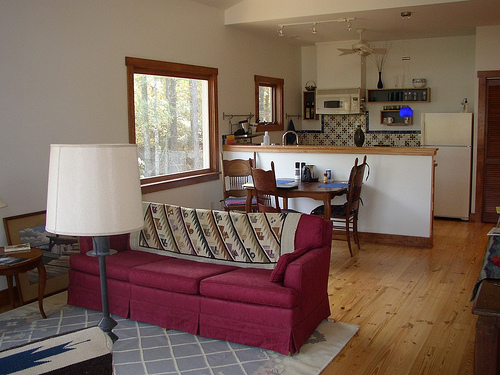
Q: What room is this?
A: It is a kitchen.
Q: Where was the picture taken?
A: It was taken at the kitchen.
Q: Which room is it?
A: It is a kitchen.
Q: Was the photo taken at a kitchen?
A: Yes, it was taken in a kitchen.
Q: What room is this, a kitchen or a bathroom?
A: It is a kitchen.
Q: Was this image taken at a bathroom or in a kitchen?
A: It was taken at a kitchen.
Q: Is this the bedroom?
A: No, it is the kitchen.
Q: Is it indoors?
A: Yes, it is indoors.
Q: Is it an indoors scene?
A: Yes, it is indoors.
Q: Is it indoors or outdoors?
A: It is indoors.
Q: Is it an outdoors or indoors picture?
A: It is indoors.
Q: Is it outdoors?
A: No, it is indoors.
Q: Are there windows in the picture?
A: Yes, there is a window.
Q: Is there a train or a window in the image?
A: Yes, there is a window.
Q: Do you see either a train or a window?
A: Yes, there is a window.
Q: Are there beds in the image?
A: No, there are no beds.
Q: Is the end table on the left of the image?
A: Yes, the end table is on the left of the image.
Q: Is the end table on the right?
A: No, the end table is on the left of the image.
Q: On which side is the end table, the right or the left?
A: The end table is on the left of the image.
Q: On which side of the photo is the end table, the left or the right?
A: The end table is on the left of the image.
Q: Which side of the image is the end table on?
A: The end table is on the left of the image.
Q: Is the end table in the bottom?
A: Yes, the end table is in the bottom of the image.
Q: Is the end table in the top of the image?
A: No, the end table is in the bottom of the image.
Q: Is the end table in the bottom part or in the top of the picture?
A: The end table is in the bottom of the image.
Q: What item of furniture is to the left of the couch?
A: The piece of furniture is an end table.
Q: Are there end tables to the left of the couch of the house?
A: Yes, there is an end table to the left of the couch.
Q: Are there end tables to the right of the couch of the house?
A: No, the end table is to the left of the couch.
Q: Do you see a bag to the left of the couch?
A: No, there is an end table to the left of the couch.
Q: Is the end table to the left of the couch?
A: Yes, the end table is to the left of the couch.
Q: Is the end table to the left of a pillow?
A: No, the end table is to the left of the couch.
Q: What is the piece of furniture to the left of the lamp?
A: The piece of furniture is an end table.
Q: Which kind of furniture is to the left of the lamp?
A: The piece of furniture is an end table.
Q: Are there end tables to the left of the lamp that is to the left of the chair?
A: Yes, there is an end table to the left of the lamp.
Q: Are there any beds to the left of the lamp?
A: No, there is an end table to the left of the lamp.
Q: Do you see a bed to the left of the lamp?
A: No, there is an end table to the left of the lamp.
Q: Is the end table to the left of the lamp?
A: Yes, the end table is to the left of the lamp.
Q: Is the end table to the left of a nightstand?
A: No, the end table is to the left of the lamp.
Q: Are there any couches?
A: Yes, there is a couch.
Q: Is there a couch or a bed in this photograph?
A: Yes, there is a couch.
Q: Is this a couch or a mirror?
A: This is a couch.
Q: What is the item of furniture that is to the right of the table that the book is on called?
A: The piece of furniture is a couch.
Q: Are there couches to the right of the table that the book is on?
A: Yes, there is a couch to the right of the table.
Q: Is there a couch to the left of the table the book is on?
A: No, the couch is to the right of the table.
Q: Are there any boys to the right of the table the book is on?
A: No, there is a couch to the right of the table.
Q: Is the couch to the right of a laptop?
A: No, the couch is to the right of the table.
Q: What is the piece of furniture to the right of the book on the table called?
A: The piece of furniture is a couch.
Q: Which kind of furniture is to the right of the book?
A: The piece of furniture is a couch.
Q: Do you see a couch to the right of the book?
A: Yes, there is a couch to the right of the book.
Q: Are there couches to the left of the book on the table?
A: No, the couch is to the right of the book.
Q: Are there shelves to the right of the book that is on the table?
A: No, there is a couch to the right of the book.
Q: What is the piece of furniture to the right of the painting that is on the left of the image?
A: The piece of furniture is a couch.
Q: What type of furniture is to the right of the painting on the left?
A: The piece of furniture is a couch.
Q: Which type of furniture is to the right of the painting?
A: The piece of furniture is a couch.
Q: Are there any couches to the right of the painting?
A: Yes, there is a couch to the right of the painting.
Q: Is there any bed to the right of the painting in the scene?
A: No, there is a couch to the right of the painting.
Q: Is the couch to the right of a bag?
A: No, the couch is to the right of a painting.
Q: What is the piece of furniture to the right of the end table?
A: The piece of furniture is a couch.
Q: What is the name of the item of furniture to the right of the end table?
A: The piece of furniture is a couch.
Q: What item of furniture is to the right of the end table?
A: The piece of furniture is a couch.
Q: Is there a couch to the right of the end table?
A: Yes, there is a couch to the right of the end table.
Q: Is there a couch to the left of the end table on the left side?
A: No, the couch is to the right of the end table.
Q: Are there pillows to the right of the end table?
A: No, there is a couch to the right of the end table.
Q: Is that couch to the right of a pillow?
A: No, the couch is to the right of an end table.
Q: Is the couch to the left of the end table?
A: No, the couch is to the right of the end table.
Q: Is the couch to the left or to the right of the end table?
A: The couch is to the right of the end table.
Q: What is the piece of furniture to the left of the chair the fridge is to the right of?
A: The piece of furniture is a couch.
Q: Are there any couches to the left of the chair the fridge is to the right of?
A: Yes, there is a couch to the left of the chair.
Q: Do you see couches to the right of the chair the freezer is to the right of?
A: No, the couch is to the left of the chair.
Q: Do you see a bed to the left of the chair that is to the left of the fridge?
A: No, there is a couch to the left of the chair.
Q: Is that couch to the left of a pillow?
A: No, the couch is to the left of a chair.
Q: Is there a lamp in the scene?
A: Yes, there is a lamp.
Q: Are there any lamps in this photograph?
A: Yes, there is a lamp.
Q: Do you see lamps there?
A: Yes, there is a lamp.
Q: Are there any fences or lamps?
A: Yes, there is a lamp.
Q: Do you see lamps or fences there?
A: Yes, there is a lamp.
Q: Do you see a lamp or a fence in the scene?
A: Yes, there is a lamp.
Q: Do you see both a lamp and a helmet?
A: No, there is a lamp but no helmets.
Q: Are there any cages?
A: No, there are no cages.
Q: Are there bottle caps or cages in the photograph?
A: No, there are no cages or bottle caps.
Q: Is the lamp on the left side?
A: Yes, the lamp is on the left of the image.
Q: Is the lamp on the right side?
A: No, the lamp is on the left of the image.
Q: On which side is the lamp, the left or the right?
A: The lamp is on the left of the image.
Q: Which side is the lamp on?
A: The lamp is on the left of the image.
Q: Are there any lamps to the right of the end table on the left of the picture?
A: Yes, there is a lamp to the right of the end table.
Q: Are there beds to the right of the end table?
A: No, there is a lamp to the right of the end table.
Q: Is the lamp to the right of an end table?
A: Yes, the lamp is to the right of an end table.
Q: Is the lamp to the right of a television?
A: No, the lamp is to the right of an end table.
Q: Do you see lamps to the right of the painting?
A: Yes, there is a lamp to the right of the painting.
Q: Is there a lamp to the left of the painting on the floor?
A: No, the lamp is to the right of the painting.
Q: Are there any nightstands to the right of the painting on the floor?
A: No, there is a lamp to the right of the painting.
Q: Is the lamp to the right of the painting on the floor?
A: Yes, the lamp is to the right of the painting.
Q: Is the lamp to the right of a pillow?
A: No, the lamp is to the right of the painting.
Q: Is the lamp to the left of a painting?
A: No, the lamp is to the right of a painting.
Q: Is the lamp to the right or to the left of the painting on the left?
A: The lamp is to the right of the painting.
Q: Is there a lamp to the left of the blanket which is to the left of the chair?
A: Yes, there is a lamp to the left of the blanket.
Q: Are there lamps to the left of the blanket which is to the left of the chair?
A: Yes, there is a lamp to the left of the blanket.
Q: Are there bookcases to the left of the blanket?
A: No, there is a lamp to the left of the blanket.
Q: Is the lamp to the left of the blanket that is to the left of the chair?
A: Yes, the lamp is to the left of the blanket.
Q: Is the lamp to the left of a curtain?
A: No, the lamp is to the left of the blanket.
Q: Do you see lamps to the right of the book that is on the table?
A: Yes, there is a lamp to the right of the book.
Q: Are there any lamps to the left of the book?
A: No, the lamp is to the right of the book.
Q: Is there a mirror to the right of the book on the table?
A: No, there is a lamp to the right of the book.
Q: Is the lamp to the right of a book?
A: Yes, the lamp is to the right of a book.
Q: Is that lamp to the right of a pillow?
A: No, the lamp is to the right of a book.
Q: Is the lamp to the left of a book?
A: No, the lamp is to the right of a book.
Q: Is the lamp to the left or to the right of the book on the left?
A: The lamp is to the right of the book.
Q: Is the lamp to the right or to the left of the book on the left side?
A: The lamp is to the right of the book.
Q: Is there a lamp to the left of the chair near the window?
A: Yes, there is a lamp to the left of the chair.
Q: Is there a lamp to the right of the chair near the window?
A: No, the lamp is to the left of the chair.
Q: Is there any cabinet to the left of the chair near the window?
A: No, there is a lamp to the left of the chair.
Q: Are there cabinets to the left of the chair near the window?
A: No, there is a lamp to the left of the chair.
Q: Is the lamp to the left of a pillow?
A: No, the lamp is to the left of the chair.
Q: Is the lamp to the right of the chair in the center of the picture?
A: No, the lamp is to the left of the chair.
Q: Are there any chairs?
A: Yes, there is a chair.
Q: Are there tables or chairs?
A: Yes, there is a chair.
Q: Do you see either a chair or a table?
A: Yes, there is a chair.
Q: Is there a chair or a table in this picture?
A: Yes, there is a chair.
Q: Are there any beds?
A: No, there are no beds.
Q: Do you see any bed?
A: No, there are no beds.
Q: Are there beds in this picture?
A: No, there are no beds.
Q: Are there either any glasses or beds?
A: No, there are no beds or glasses.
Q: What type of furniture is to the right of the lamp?
A: The piece of furniture is a chair.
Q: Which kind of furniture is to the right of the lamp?
A: The piece of furniture is a chair.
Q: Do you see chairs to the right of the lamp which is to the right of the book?
A: Yes, there is a chair to the right of the lamp.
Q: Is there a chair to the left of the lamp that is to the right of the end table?
A: No, the chair is to the right of the lamp.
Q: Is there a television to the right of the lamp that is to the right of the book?
A: No, there is a chair to the right of the lamp.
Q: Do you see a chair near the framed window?
A: Yes, there is a chair near the window.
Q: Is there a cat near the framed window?
A: No, there is a chair near the window.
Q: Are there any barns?
A: No, there are no barns.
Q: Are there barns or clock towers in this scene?
A: No, there are no barns or clock towers.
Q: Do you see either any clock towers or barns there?
A: No, there are no barns or clock towers.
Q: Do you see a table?
A: Yes, there is a table.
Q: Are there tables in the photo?
A: Yes, there is a table.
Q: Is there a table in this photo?
A: Yes, there is a table.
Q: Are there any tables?
A: Yes, there is a table.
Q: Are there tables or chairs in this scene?
A: Yes, there is a table.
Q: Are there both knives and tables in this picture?
A: No, there is a table but no knives.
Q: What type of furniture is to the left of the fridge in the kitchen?
A: The piece of furniture is a table.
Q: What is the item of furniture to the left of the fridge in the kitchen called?
A: The piece of furniture is a table.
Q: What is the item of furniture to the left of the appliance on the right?
A: The piece of furniture is a table.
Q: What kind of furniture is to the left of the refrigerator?
A: The piece of furniture is a table.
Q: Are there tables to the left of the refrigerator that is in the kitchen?
A: Yes, there is a table to the left of the fridge.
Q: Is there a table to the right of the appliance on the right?
A: No, the table is to the left of the freezer.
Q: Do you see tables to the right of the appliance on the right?
A: No, the table is to the left of the freezer.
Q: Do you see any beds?
A: No, there are no beds.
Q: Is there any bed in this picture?
A: No, there are no beds.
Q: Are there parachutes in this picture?
A: No, there are no parachutes.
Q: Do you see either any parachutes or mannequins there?
A: No, there are no parachutes or mannequins.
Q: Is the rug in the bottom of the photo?
A: Yes, the rug is in the bottom of the image.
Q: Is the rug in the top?
A: No, the rug is in the bottom of the image.